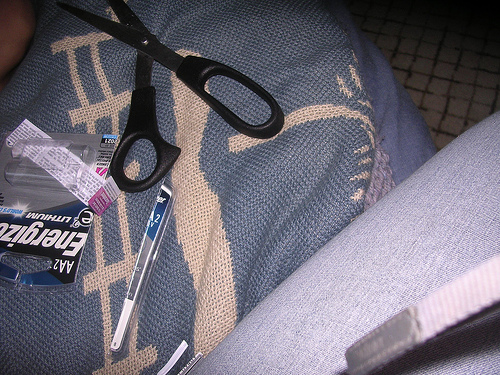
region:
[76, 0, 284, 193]
a black pair of scissors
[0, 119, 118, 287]
a package of Energizer batteries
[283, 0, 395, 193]
a knit bed blanket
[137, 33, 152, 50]
the screw connection on the scissors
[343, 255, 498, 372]
a cloth strap for a bag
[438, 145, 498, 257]
a sofa cloth cover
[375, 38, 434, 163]
a blue bed sheet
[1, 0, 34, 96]
a persons knee on the bed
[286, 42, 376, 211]
a beige knit design on the blanket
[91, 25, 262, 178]
scissors on a cushion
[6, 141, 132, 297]
plastic on a cushion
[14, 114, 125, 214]
label on the bed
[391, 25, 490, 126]
tiles on the floor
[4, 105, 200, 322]
scissors on the bed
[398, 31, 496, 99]
dirt in the tile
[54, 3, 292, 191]
a pair of black scissors on a pillow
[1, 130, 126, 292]
opened pack of energizer batteries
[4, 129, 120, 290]
empty package of double a batteries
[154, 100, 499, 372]
person's leg wearing jeans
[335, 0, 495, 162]
tile on the floor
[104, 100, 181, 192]
thumb hole for the scissors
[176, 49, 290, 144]
fingers hole for the scissors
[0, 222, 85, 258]
brand symbol on the battery package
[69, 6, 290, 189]
black plastic handled scissors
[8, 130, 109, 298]
empty packaging for AA batteries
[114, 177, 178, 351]
strip of plastic battery packaging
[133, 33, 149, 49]
shiny circular screw on scissors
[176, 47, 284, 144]
one oval shaped scissors handle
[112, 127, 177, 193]
one black circular scissors handle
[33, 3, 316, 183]
pair of scissors on top of blue blanket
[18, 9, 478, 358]
objects on one person's lap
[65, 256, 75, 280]
upside down white letter A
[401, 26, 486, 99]
section of beige square tiled floor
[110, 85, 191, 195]
the handle of the scissor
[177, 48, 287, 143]
the large black handle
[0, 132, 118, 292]
the case is opened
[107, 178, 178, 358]
the plastic strip on the lap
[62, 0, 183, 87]
the blades of the scissors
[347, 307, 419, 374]
the leather strip on the strap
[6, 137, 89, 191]
the plastic on the packageing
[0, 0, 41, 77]
the skin of the person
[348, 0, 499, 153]
the floor is a light brown